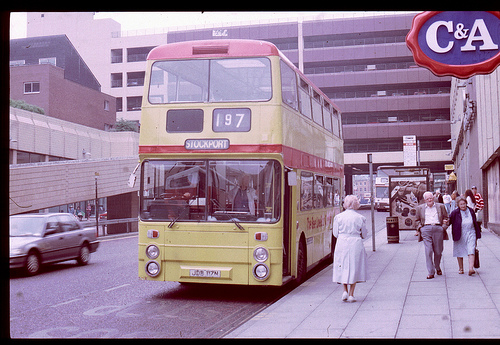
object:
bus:
[136, 38, 342, 298]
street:
[7, 181, 409, 333]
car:
[9, 211, 98, 278]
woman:
[330, 194, 367, 301]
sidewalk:
[224, 213, 499, 342]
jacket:
[331, 211, 367, 286]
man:
[418, 191, 445, 278]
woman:
[447, 197, 479, 279]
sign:
[404, 11, 500, 78]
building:
[445, 79, 500, 235]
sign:
[213, 110, 251, 134]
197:
[215, 112, 247, 127]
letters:
[425, 19, 496, 56]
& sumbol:
[451, 23, 468, 41]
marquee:
[185, 139, 230, 148]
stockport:
[187, 141, 227, 148]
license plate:
[189, 269, 222, 279]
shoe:
[341, 291, 349, 302]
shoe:
[348, 295, 356, 304]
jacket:
[449, 208, 482, 242]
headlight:
[141, 244, 158, 256]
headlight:
[143, 261, 161, 274]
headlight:
[251, 247, 268, 261]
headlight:
[252, 263, 267, 279]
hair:
[342, 193, 361, 212]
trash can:
[385, 214, 401, 245]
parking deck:
[28, 14, 451, 208]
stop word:
[31, 322, 173, 338]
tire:
[299, 236, 310, 280]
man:
[471, 183, 485, 231]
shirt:
[471, 192, 483, 209]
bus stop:
[386, 172, 432, 232]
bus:
[368, 168, 395, 209]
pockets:
[434, 226, 446, 237]